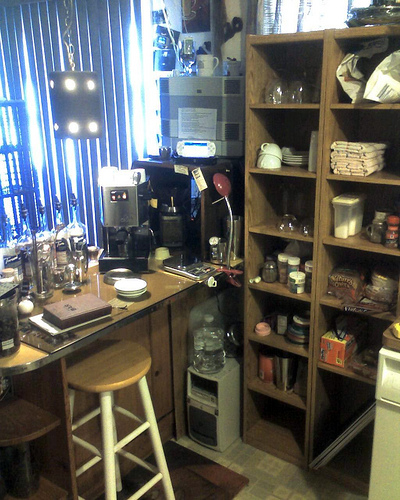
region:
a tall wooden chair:
[60, 324, 164, 496]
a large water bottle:
[188, 305, 224, 377]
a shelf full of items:
[236, 17, 396, 465]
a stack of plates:
[105, 273, 157, 298]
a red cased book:
[34, 281, 115, 333]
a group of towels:
[332, 130, 384, 181]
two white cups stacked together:
[252, 139, 287, 174]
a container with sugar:
[329, 190, 362, 234]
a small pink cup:
[251, 316, 271, 343]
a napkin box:
[320, 313, 368, 365]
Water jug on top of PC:
[190, 308, 228, 371]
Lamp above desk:
[44, 1, 108, 141]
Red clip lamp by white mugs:
[208, 168, 246, 288]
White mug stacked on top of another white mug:
[252, 136, 288, 160]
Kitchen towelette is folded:
[328, 132, 385, 154]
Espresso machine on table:
[94, 164, 153, 272]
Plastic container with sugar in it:
[325, 192, 365, 240]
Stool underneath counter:
[61, 338, 189, 498]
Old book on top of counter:
[37, 290, 113, 328]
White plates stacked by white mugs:
[280, 145, 310, 170]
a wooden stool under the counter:
[57, 337, 177, 499]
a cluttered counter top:
[0, 254, 248, 372]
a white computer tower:
[187, 347, 241, 452]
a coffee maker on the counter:
[97, 166, 154, 272]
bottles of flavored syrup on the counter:
[0, 189, 88, 297]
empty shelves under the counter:
[0, 399, 72, 499]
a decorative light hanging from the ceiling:
[50, 68, 104, 140]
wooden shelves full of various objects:
[241, 24, 398, 492]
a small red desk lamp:
[209, 170, 241, 289]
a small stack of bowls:
[114, 276, 145, 298]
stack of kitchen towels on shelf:
[334, 142, 386, 173]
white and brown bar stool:
[67, 346, 171, 498]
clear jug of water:
[199, 313, 223, 365]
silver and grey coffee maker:
[95, 166, 146, 265]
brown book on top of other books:
[46, 302, 109, 323]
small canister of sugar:
[335, 190, 363, 243]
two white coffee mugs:
[258, 140, 280, 168]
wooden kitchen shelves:
[247, 73, 397, 482]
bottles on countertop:
[14, 197, 86, 294]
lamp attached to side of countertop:
[210, 173, 239, 289]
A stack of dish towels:
[332, 133, 390, 184]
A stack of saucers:
[111, 274, 152, 296]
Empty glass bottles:
[1, 189, 101, 284]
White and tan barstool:
[71, 336, 155, 498]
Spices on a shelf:
[334, 189, 399, 250]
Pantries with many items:
[248, 28, 376, 347]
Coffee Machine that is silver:
[92, 169, 149, 262]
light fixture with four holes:
[38, 69, 118, 145]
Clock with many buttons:
[172, 130, 220, 155]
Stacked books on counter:
[39, 289, 130, 342]